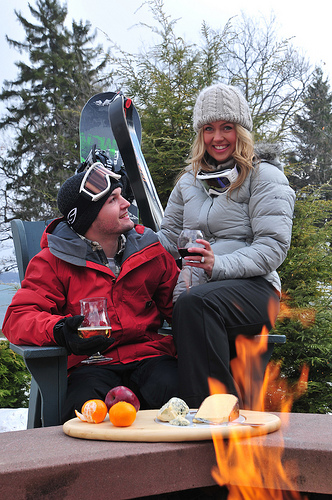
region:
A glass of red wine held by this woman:
[177, 225, 206, 285]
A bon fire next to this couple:
[238, 356, 293, 494]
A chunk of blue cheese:
[155, 397, 191, 424]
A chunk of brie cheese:
[199, 394, 241, 427]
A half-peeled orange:
[79, 395, 106, 422]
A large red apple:
[106, 386, 141, 401]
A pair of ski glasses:
[79, 164, 119, 192]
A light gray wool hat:
[189, 83, 253, 123]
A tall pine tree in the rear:
[20, 41, 65, 176]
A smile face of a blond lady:
[186, 115, 266, 165]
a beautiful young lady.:
[145, 79, 300, 406]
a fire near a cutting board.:
[205, 290, 323, 498]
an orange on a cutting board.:
[105, 396, 142, 430]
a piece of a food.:
[197, 383, 242, 428]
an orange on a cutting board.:
[78, 394, 106, 424]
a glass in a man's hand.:
[73, 294, 122, 367]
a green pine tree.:
[0, 0, 123, 224]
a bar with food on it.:
[0, 407, 331, 499]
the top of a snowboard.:
[108, 82, 160, 171]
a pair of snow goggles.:
[184, 148, 256, 202]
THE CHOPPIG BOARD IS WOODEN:
[157, 421, 159, 442]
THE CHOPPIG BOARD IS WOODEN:
[144, 430, 152, 439]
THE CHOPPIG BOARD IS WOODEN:
[148, 429, 155, 444]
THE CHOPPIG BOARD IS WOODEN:
[147, 417, 157, 443]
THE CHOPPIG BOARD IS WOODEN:
[142, 429, 148, 439]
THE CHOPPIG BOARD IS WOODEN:
[146, 431, 154, 438]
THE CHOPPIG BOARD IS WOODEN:
[148, 426, 161, 446]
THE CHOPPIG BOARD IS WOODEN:
[153, 434, 165, 450]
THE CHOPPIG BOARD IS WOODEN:
[143, 434, 155, 447]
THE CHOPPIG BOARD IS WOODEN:
[145, 428, 155, 437]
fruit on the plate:
[64, 374, 137, 429]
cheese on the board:
[162, 394, 237, 430]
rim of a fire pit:
[7, 423, 140, 490]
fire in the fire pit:
[210, 343, 312, 498]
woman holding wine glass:
[166, 227, 225, 300]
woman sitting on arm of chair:
[185, 77, 306, 364]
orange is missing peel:
[65, 394, 105, 426]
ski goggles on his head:
[83, 155, 123, 248]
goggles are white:
[187, 169, 259, 196]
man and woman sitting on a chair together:
[0, 80, 293, 401]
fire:
[203, 293, 317, 495]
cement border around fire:
[3, 415, 329, 498]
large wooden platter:
[58, 408, 281, 441]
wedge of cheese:
[192, 389, 239, 421]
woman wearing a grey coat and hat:
[158, 83, 291, 283]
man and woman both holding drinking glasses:
[44, 86, 268, 357]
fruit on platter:
[73, 384, 145, 435]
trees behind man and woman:
[5, 1, 331, 408]